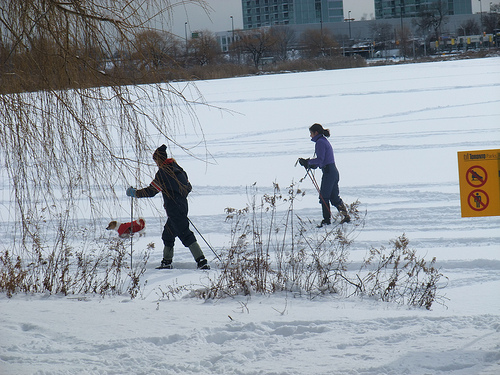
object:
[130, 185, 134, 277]
ski pole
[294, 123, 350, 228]
girl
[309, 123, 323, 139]
head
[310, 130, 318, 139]
face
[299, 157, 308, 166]
hand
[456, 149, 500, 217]
signals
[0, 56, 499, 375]
ice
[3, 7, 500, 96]
trees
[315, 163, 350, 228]
legs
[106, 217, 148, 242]
dog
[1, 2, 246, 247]
tree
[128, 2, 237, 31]
sky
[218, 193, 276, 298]
plant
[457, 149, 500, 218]
board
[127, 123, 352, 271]
people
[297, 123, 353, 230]
woman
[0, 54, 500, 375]
snow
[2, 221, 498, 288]
trail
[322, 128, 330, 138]
bun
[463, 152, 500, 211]
sign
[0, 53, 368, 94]
grass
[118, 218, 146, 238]
outfit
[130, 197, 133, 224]
leash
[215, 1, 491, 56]
building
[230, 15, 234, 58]
lamp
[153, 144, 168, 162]
hat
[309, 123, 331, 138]
hair